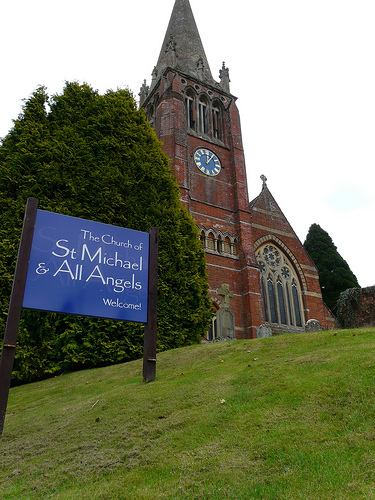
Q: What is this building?
A: Church.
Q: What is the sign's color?
A: Blue.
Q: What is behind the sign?
A: Tree.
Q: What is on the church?
A: Clock.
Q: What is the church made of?
A: Brick.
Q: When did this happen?
A: During the day time.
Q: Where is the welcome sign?
A: Front of church.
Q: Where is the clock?
A: Tower.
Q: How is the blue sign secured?
A: Black pole.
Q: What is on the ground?
A: Grass.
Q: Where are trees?
A: Either side of church.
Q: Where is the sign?
A: Grass.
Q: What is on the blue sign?
A: A welcome.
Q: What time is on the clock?
A: 12:05.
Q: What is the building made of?
A: Brick.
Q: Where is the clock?
A: On the building.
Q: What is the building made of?
A: Brick.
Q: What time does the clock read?
A: 12:05.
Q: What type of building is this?
A: A church.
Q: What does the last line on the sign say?
A: Welcome.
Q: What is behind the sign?
A: A bush.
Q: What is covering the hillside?
A: Grass.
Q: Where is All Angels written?
A: On the sign.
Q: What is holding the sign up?
A: Two posts.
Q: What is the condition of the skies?
A: Overcast.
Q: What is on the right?
A: Sign.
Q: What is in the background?
A: Church.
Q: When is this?
A: Daytime.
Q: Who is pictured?
A: Nobody.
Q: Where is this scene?
A: Church lawn.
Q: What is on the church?
A: Clock.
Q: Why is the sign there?
A: Information.